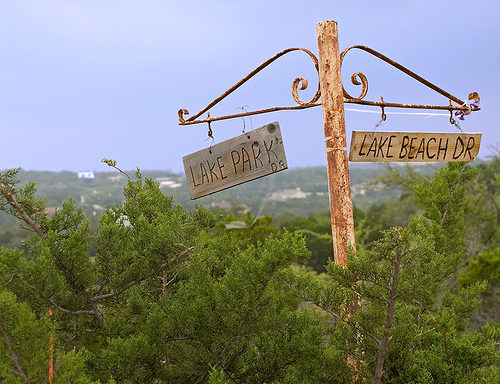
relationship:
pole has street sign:
[317, 20, 360, 268] [179, 118, 293, 204]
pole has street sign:
[317, 20, 360, 268] [348, 135, 485, 165]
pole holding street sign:
[317, 20, 360, 268] [179, 118, 293, 204]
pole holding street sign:
[317, 20, 360, 268] [348, 135, 485, 165]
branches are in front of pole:
[3, 159, 498, 383] [317, 20, 360, 268]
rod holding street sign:
[175, 48, 322, 127] [179, 118, 293, 204]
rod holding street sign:
[336, 46, 481, 114] [348, 135, 485, 165]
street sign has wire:
[179, 118, 293, 204] [207, 111, 250, 140]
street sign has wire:
[348, 135, 485, 165] [375, 101, 469, 133]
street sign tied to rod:
[348, 135, 485, 165] [336, 46, 481, 114]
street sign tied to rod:
[179, 118, 293, 204] [175, 48, 322, 127]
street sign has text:
[348, 135, 485, 165] [359, 137, 476, 159]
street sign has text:
[179, 118, 293, 204] [190, 137, 282, 186]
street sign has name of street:
[179, 118, 293, 204] [190, 137, 282, 186]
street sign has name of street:
[348, 135, 485, 165] [359, 137, 476, 159]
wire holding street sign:
[207, 111, 250, 140] [179, 118, 293, 204]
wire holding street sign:
[375, 101, 469, 133] [348, 135, 485, 165]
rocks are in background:
[42, 176, 383, 236] [1, 167, 498, 250]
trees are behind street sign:
[230, 154, 499, 268] [179, 118, 293, 204]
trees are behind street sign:
[230, 154, 499, 268] [348, 135, 485, 165]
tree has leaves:
[6, 175, 192, 381] [5, 174, 159, 331]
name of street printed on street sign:
[190, 137, 282, 186] [179, 118, 293, 204]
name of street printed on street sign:
[359, 137, 476, 159] [348, 135, 485, 165]